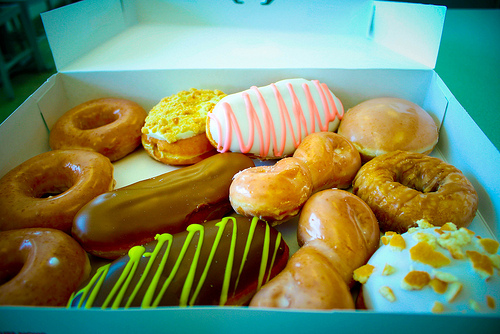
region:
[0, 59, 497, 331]
Box of donuts on the table.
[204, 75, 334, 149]
Pink and white glaze on donut.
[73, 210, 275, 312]
Brown and yellow glazed donut.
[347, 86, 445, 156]
Glazed puff donut.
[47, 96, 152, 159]
Glazed donut with hole in center.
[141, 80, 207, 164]
Sprinkled yellow topping on donut.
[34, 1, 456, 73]
White box lid for donuts.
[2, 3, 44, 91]
Gray cart in the background.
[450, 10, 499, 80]
Gray table under donut box.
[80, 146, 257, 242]
Long brown glazed donut.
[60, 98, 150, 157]
Round glazed donut in box.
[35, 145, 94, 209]
Round glazed donut in box.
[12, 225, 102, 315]
Round glazed donut in box.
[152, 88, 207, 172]
White and yellow topping on round donut.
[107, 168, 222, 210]
Long brown donut in box.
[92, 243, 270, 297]
Brown and yellow frosting on donut.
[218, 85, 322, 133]
Pink and white frosting on donut.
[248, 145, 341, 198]
Glazed donut in box.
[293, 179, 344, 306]
Long glazed donut in box.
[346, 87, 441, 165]
Round glazed donut in box.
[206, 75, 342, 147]
a vanilla frosted donut with orange stripes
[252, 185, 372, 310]
a sugar glazed donut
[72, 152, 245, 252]
a chocolate custard filled eclair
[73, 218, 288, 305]
a chocolate eclair with green icing stripes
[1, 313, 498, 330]
a green dozen doughnut box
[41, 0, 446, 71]
the inside cover of the doughnut box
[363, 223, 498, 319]
a custard filled vanilla doughnut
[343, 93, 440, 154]
a jelly filled sugar glazed doughnut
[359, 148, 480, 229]
a cake glazed doughnut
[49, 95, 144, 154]
a round sugar glazed donut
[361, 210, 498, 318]
white glazed doughnut with nuts on top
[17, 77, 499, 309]
assorted doughnuts in white box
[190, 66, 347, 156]
doughnut with pink drizzle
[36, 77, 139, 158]
glazed doughnut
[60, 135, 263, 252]
chocolate eclair in white box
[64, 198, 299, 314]
chocolate eclair with yellow drizzle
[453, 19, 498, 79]
green table top surface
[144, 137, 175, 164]
filling hole in side of doughnut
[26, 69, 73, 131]
cardboard flap on side of white box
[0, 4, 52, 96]
green chair legs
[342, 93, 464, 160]
the donut is grazed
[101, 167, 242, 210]
the donut is covered with choclate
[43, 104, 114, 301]
the donuts are three in total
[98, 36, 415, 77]
the box is white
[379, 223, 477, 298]
the topping is brown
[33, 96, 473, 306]
the donuts are delicious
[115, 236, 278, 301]
thetopping is geen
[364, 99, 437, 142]
the surface is shiny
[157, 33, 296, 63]
light is on the box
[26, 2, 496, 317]
the box is open